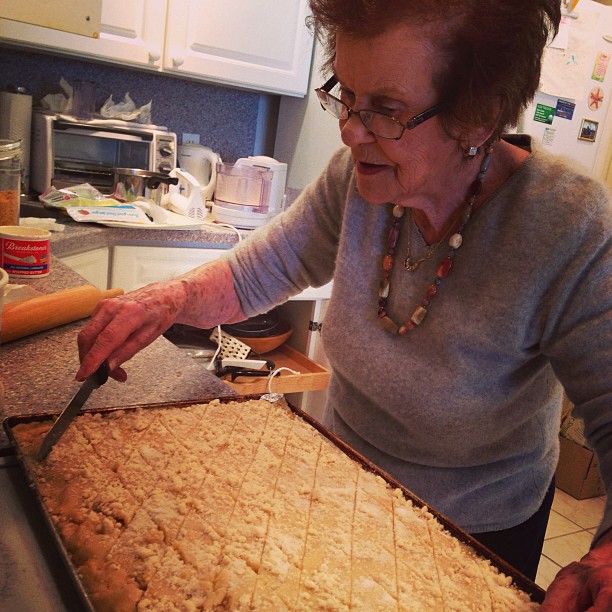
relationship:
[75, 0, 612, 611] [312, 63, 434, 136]
woman wears glasses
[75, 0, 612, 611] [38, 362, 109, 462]
woman holding knife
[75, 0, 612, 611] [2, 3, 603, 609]
woman in kitchen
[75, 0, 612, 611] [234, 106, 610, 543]
woman wearing shirt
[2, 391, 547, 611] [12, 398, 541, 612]
pan of baked goods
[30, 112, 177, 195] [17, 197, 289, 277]
microwave oven on counter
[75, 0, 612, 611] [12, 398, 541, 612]
woman cutting into baked goods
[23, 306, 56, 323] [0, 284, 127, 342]
brown wooden rolling brown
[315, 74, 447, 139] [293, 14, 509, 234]
eyeglasses on face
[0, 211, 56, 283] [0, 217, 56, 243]
containerr of icing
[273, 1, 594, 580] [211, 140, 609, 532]
woman wearing shirt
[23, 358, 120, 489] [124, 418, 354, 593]
knife cutting into baked goods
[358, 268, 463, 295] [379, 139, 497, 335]
large beads on a large beads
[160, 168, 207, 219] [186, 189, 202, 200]
mixer hand mixer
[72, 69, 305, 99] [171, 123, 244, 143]
closed white cupboard doors